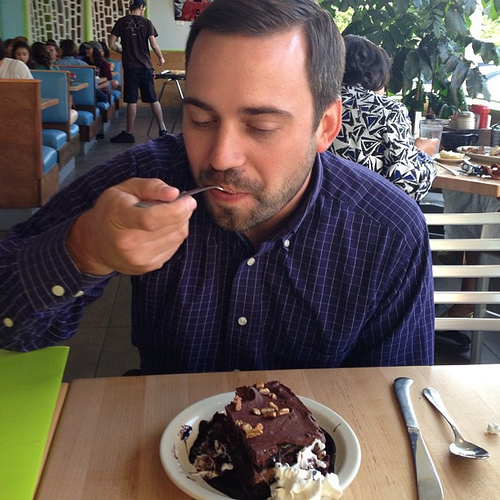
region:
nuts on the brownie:
[242, 411, 270, 441]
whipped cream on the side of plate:
[281, 474, 315, 497]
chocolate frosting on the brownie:
[246, 439, 283, 466]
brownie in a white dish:
[172, 437, 240, 479]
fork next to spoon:
[385, 418, 432, 491]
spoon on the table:
[425, 428, 484, 478]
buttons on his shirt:
[234, 233, 260, 328]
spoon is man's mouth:
[187, 170, 254, 218]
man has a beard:
[228, 182, 293, 225]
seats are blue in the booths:
[58, 82, 63, 147]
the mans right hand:
[84, 176, 198, 279]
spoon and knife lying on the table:
[390, 369, 488, 498]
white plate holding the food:
[157, 390, 364, 498]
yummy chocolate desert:
[193, 379, 333, 498]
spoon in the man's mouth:
[131, 180, 238, 210]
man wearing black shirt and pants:
[106, 1, 173, 146]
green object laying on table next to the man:
[0, 340, 74, 498]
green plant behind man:
[321, 1, 498, 128]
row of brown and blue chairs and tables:
[10, 59, 126, 195]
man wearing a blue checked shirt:
[0, 1, 435, 366]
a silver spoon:
[423, 385, 490, 464]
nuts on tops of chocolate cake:
[231, 385, 286, 438]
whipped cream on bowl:
[270, 462, 343, 499]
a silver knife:
[393, 374, 449, 499]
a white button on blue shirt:
[236, 314, 248, 328]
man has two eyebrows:
[178, 92, 295, 119]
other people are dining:
[1, 30, 121, 130]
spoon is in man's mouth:
[200, 177, 252, 204]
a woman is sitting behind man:
[341, 35, 435, 197]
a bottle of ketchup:
[470, 100, 487, 137]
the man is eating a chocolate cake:
[4, 3, 484, 498]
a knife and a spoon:
[384, 365, 495, 498]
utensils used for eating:
[380, 370, 499, 497]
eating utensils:
[383, 368, 487, 499]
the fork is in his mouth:
[124, 155, 251, 223]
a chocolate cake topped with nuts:
[153, 374, 328, 490]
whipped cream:
[257, 459, 359, 497]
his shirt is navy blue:
[40, 133, 465, 380]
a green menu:
[3, 348, 71, 497]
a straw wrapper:
[481, 415, 498, 445]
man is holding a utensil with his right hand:
[147, 165, 298, 260]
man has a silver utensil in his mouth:
[80, 1, 341, 272]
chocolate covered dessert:
[205, 387, 317, 472]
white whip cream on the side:
[273, 460, 336, 496]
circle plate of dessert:
[160, 391, 361, 496]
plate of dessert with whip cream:
[162, 376, 362, 492]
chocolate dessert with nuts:
[146, 383, 366, 490]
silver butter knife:
[400, 370, 437, 496]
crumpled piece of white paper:
[475, 416, 496, 436]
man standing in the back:
[108, 5, 160, 137]